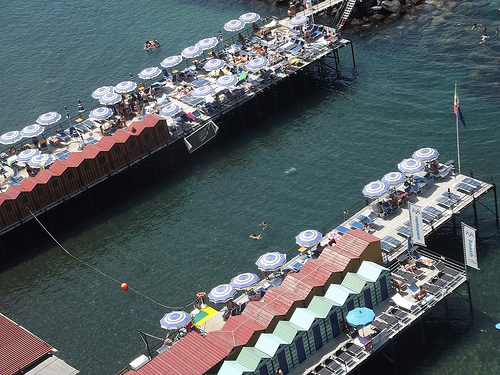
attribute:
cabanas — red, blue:
[197, 222, 404, 374]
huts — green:
[238, 261, 397, 372]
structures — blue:
[213, 255, 394, 373]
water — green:
[185, 192, 235, 256]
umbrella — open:
[412, 147, 437, 160]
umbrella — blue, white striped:
[360, 179, 387, 209]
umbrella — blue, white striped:
[383, 165, 403, 195]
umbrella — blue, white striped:
[397, 156, 422, 191]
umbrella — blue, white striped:
[412, 145, 439, 172]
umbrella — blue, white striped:
[293, 225, 325, 252]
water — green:
[2, 5, 496, 374]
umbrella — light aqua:
[161, 51, 181, 71]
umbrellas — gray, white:
[233, 10, 258, 32]